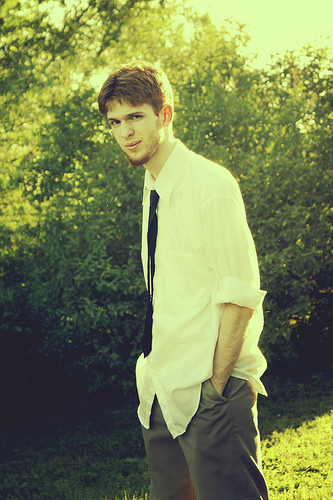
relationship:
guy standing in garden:
[98, 62, 269, 498] [0, 0, 332, 500]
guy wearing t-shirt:
[98, 62, 269, 498] [134, 138, 268, 439]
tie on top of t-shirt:
[142, 190, 160, 358] [134, 138, 268, 439]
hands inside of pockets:
[194, 304, 254, 450] [191, 378, 231, 453]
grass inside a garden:
[1, 375, 331, 499] [0, 0, 332, 500]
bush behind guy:
[229, 48, 332, 364] [98, 62, 269, 498]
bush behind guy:
[2, 19, 316, 395] [98, 62, 269, 498]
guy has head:
[98, 62, 269, 498] [98, 60, 174, 167]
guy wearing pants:
[98, 62, 269, 498] [139, 376, 268, 500]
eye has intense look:
[131, 114, 143, 121] [107, 113, 143, 129]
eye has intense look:
[112, 118, 120, 125] [107, 113, 143, 129]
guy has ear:
[98, 62, 269, 498] [161, 104, 173, 127]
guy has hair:
[98, 62, 269, 498] [98, 62, 173, 117]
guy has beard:
[98, 62, 269, 498] [118, 116, 162, 165]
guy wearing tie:
[98, 62, 269, 498] [142, 190, 160, 358]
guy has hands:
[98, 62, 269, 498] [194, 304, 254, 450]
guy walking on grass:
[98, 62, 269, 498] [1, 375, 331, 499]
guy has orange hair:
[98, 62, 269, 498] [98, 62, 173, 117]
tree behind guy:
[1, 0, 166, 140] [98, 62, 269, 498]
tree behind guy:
[0, 0, 250, 176] [98, 62, 269, 498]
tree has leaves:
[1, 0, 166, 140] [1, 1, 167, 139]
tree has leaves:
[0, 0, 250, 176] [0, 0, 251, 175]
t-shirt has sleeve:
[134, 138, 268, 439] [201, 193, 267, 311]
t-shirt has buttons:
[134, 138, 268, 439] [144, 177, 178, 440]